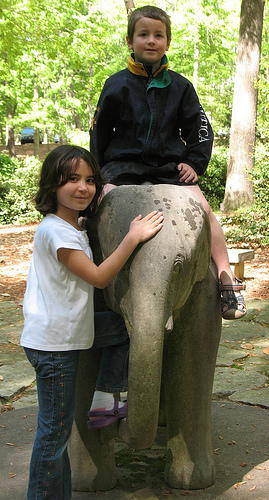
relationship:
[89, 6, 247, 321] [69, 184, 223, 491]
boy sitting on elephant statue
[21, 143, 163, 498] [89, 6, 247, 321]
children near boy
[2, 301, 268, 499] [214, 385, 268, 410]
stone with cracks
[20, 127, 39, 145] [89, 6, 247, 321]
car behind boy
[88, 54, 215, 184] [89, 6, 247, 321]
coat being worn by boy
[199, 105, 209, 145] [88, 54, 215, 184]
letters on coat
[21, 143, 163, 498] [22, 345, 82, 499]
children in jeans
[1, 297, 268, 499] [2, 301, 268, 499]
shadows on stone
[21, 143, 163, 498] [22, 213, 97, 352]
children in white shirt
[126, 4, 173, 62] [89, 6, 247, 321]
head of boy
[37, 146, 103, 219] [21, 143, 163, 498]
head of children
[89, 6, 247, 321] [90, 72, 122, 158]
boy right arm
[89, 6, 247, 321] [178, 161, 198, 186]
boy left hand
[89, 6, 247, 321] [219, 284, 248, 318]
boy left foot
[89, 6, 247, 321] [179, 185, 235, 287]
boy has left leg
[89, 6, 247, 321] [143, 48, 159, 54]
boy has a mouth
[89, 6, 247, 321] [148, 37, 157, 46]
boy has a nose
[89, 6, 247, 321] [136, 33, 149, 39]
boy has right eye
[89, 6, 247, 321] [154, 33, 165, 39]
boy has left eye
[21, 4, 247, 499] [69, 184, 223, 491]
children near elephant statue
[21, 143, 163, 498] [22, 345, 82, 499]
children wearing blue jeans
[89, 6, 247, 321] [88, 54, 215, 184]
boy wearing coat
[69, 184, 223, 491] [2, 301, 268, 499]
elephant statue on top of stone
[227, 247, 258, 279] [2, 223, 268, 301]
bench on top of dirt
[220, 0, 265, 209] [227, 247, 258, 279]
tree behind bench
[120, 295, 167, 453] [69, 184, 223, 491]
trunk of elephant statue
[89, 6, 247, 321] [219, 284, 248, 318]
boy has left shoe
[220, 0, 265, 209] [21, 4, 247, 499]
tree behind children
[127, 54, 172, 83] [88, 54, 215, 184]
collar on boys coat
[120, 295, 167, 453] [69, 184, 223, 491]
trunk on elephant statue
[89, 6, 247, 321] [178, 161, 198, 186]
boy has a left hand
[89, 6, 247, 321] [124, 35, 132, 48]
boy has a right ear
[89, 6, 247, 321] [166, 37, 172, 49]
boy has a left ear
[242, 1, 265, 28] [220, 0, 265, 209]
bark on a tree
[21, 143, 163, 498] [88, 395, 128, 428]
children wearing purple sandles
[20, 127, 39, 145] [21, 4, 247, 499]
car behind children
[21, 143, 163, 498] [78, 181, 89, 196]
children has a nose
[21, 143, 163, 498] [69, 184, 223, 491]
children standing near elephant statue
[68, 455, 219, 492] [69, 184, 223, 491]
hoofs of an elephant statue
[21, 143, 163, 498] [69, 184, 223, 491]
children near elephant statue